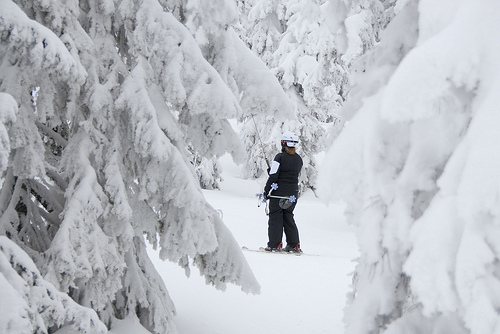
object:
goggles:
[281, 138, 300, 147]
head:
[278, 133, 302, 155]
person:
[262, 132, 306, 258]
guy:
[263, 131, 303, 252]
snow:
[211, 188, 350, 330]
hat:
[279, 131, 302, 142]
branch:
[119, 65, 260, 293]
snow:
[123, 68, 205, 234]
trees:
[3, 4, 281, 305]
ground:
[138, 188, 343, 332]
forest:
[3, 16, 496, 331]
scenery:
[25, 10, 360, 228]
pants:
[266, 194, 302, 248]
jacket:
[264, 153, 305, 198]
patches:
[268, 161, 280, 174]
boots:
[282, 243, 304, 252]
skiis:
[241, 246, 318, 258]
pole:
[247, 108, 274, 176]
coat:
[263, 154, 304, 197]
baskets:
[271, 182, 295, 201]